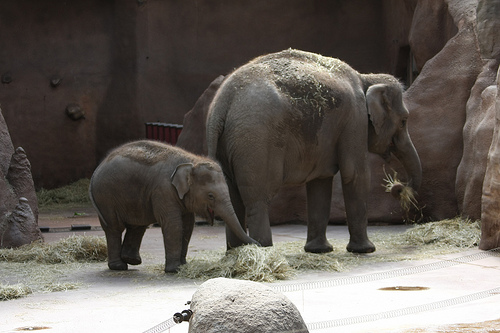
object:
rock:
[186, 271, 310, 333]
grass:
[270, 52, 343, 105]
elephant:
[205, 48, 376, 256]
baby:
[87, 140, 180, 223]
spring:
[171, 307, 192, 324]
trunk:
[380, 169, 423, 211]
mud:
[376, 285, 430, 293]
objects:
[62, 98, 89, 121]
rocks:
[402, 21, 481, 217]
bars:
[144, 120, 185, 147]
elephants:
[86, 140, 261, 274]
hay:
[390, 156, 429, 207]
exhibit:
[34, 19, 489, 244]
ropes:
[34, 224, 100, 236]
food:
[201, 243, 292, 279]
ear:
[169, 164, 191, 199]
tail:
[204, 82, 229, 158]